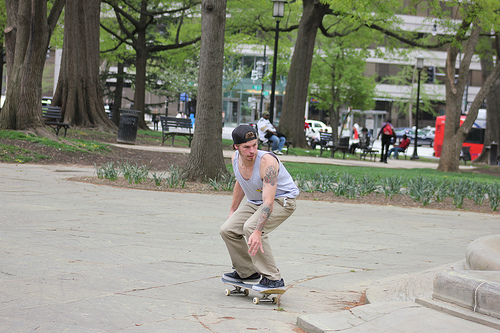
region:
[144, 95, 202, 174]
a black park bench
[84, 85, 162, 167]
a black trash can in a park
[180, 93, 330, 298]
a man skateboarding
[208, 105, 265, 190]
a man wearing his hat backwards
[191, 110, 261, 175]
a man wearing a black hat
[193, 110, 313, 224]
a man wearing a gray tank top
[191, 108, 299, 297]
a man wearing tan pants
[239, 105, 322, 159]
a person sitting on a bench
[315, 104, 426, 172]
people walking in the park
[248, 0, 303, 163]
a black light in the park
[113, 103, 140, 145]
garbage can in the park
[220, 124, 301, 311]
young make riding a skate board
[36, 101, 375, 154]
benches located in the park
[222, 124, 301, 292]
young man with tattoos on his arm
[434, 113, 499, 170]
red bus driving in the city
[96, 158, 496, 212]
plants planted in the park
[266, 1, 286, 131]
street lamp in the park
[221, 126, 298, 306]
young male with hat on backwards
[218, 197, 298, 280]
a tan pair of long pants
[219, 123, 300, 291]
young make in a grey tank top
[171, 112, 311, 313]
a skateboarder riding a skateboard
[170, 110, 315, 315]
a man riding a skateboard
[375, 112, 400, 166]
a person wearing a red backpack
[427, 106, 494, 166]
a red city bus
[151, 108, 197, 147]
a black park bench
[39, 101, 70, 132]
a black park bench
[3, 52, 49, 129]
the trunk of an oak tree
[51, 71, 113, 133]
the trunk of an oak tree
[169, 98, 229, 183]
the trunk of an oak tree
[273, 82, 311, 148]
the trunk of an oak tree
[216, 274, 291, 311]
Man on a board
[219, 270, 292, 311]
Man on a skateboard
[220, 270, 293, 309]
Man is on a skateboard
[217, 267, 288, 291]
Man wearing shoes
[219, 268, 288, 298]
Man is wearing shoes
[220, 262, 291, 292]
Man wearing black and white shoes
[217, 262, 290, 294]
Man is wearing black and white shoes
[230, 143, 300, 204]
Man wearing a gray tank top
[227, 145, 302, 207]
Man is wearing a gray tank top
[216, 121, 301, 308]
A guy is skateboarding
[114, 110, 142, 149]
A black trash can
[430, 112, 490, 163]
A bus is red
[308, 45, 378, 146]
Green leaves on a tree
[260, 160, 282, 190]
Tattoo on an arm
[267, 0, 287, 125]
A tall street lamp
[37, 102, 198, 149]
Two empty black benches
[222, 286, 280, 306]
Four wheels of a skateboard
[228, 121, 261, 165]
Black hat on a guy's head